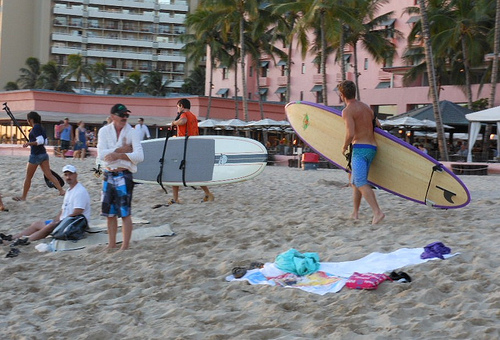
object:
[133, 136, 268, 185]
surfboard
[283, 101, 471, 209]
surfboard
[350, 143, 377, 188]
swim trunks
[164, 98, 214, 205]
man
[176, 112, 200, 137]
shirt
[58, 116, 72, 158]
man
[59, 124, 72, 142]
shirt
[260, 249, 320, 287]
towel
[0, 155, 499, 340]
sand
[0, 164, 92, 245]
man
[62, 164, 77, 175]
hat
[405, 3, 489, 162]
palm tree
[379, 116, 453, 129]
umbrella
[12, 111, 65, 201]
girl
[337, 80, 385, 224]
man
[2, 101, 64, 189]
oars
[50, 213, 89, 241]
backpack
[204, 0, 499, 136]
building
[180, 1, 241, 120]
palm trees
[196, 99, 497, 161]
dining area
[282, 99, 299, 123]
tip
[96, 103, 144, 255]
man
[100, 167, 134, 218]
shorts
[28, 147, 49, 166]
shorts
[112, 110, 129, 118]
sunglasses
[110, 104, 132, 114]
hat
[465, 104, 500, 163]
tent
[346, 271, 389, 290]
bag